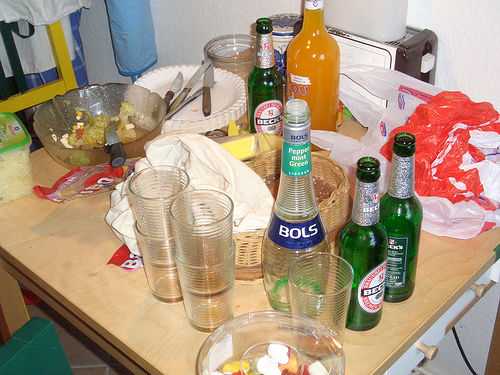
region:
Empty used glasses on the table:
[129, 162, 238, 330]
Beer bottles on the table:
[340, 129, 423, 339]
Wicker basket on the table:
[222, 149, 346, 285]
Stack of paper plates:
[128, 63, 248, 135]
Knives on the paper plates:
[161, 57, 220, 122]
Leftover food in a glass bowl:
[32, 80, 167, 170]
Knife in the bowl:
[103, 116, 129, 168]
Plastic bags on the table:
[363, 90, 497, 241]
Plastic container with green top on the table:
[0, 112, 32, 206]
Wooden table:
[0, 98, 498, 371]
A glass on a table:
[288, 249, 353, 357]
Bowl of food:
[192, 310, 344, 373]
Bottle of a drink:
[258, 99, 328, 314]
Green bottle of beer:
[339, 157, 386, 329]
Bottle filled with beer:
[247, 17, 282, 134]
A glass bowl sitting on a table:
[30, 82, 165, 167]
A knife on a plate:
[202, 58, 214, 117]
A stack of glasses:
[125, 165, 193, 302]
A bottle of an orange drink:
[282, 3, 338, 131]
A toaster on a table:
[321, 25, 439, 85]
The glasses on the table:
[122, 168, 251, 330]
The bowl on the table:
[29, 75, 169, 175]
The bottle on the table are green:
[338, 128, 425, 333]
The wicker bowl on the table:
[223, 142, 353, 283]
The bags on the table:
[389, 76, 495, 241]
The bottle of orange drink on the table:
[287, 4, 347, 154]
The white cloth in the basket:
[139, 120, 271, 229]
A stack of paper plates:
[121, 58, 251, 135]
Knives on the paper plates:
[157, 54, 217, 121]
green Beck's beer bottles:
[336, 132, 422, 330]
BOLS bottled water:
[265, 97, 330, 315]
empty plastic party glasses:
[126, 163, 233, 331]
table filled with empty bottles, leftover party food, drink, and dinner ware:
[3, 0, 496, 372]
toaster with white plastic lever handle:
[324, 25, 437, 110]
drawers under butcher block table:
[380, 256, 495, 367]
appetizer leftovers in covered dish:
[195, 310, 345, 370]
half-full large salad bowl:
[31, 80, 162, 163]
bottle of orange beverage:
[285, 0, 337, 132]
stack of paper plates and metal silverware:
[123, 63, 249, 133]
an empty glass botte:
[262, 100, 332, 318]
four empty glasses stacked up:
[128, 166, 237, 336]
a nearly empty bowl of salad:
[28, 84, 170, 173]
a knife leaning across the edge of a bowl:
[86, 107, 143, 176]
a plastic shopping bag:
[337, 52, 499, 224]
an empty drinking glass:
[284, 245, 355, 359]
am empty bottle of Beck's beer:
[245, 15, 284, 140]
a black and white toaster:
[316, 21, 439, 130]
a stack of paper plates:
[133, 49, 251, 134]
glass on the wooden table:
[125, 161, 182, 273]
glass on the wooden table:
[133, 218, 184, 305]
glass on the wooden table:
[170, 185, 232, 295]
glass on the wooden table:
[172, 250, 239, 330]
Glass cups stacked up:
[132, 176, 235, 328]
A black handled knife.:
[99, 121, 128, 169]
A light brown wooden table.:
[3, 70, 498, 373]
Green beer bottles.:
[254, 17, 421, 324]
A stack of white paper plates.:
[133, 58, 248, 135]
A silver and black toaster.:
[308, 17, 439, 112]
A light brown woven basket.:
[222, 141, 362, 261]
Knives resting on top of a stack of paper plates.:
[155, 62, 225, 122]